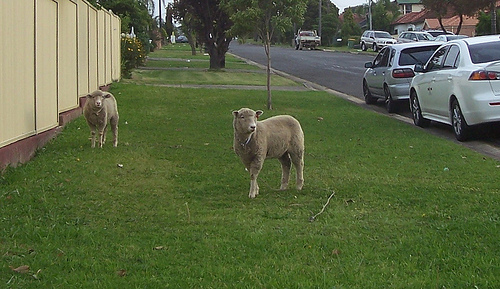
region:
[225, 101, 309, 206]
white sheep on short grass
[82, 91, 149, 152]
white sheep on short grass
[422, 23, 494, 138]
white car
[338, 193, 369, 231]
short green and yellow grass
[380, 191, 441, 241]
short green and yellow grass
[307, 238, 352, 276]
short green and yellow grass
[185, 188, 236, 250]
short green and yellow grass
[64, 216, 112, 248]
short green and yellow grass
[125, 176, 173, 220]
short green and yellow grass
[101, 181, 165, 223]
short green and yellow grass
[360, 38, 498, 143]
Cars parked on the side of the road.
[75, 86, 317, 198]
Two ships on the grass.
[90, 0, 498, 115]
Trees in the background.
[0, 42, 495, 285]
Green grass on the ground.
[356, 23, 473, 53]
Cars in the background.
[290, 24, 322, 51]
Truck in the background.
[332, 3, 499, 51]
Houses in the background.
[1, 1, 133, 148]
Cream colored fence by the animals.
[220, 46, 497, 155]
Curb along side the street.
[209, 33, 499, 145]
Blacktop on the street.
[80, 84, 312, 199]
Two sheep standing on side of road.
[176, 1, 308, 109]
Trees growing on grassy area next to street.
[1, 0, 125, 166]
Wall running next to grassy area.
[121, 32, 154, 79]
Flowering bush growing on grassy area.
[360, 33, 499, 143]
Cars parked on side of street.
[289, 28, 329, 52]
Truck parked on side of street.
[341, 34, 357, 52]
Trash can standing out by street.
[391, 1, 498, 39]
Homes along street in distance.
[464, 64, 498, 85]
Break and signal lights on rear of car.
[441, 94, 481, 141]
Left rear tire on car.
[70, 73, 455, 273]
the sheep are on the grass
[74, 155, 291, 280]
the gras sis freshly cut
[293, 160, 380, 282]
a stick is on the grass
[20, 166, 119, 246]
leaves are on the grass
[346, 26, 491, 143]
the cars are parked by the grass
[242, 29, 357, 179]
the tree is tall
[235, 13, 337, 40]
leaves are on the branches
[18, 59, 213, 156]
a wall is by the grass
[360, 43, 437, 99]
one car is silver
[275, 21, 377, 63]
a truck is parked on the street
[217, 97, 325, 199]
white sheep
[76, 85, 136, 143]
white sheep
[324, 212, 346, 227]
short green and yellow grass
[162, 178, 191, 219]
short green and yellow grass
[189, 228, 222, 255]
short green and yellow grass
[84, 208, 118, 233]
short green and yellow grass